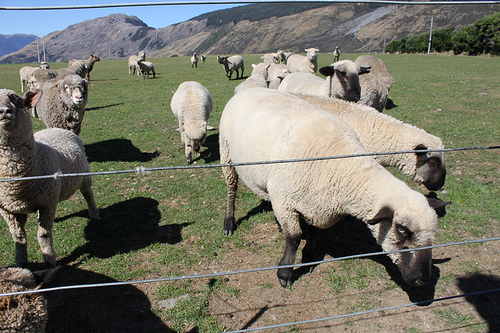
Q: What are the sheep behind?
A: Fence.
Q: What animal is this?
A: Sheep.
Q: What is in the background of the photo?
A: Mountains.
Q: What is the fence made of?
A: Metal.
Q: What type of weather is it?
A: Sunny.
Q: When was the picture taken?
A: In the day.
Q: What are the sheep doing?
A: Eating.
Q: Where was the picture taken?
A: In a sheep farm.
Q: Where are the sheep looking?
A: Ahead.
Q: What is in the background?
A: A mountain.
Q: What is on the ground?
A: Grass.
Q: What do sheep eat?
A: Grass.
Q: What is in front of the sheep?
A: Wire fence.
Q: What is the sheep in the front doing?
A: Eating.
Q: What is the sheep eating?
A: Grass.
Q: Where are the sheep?
A: Inside the fence.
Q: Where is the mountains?
A: In the distance.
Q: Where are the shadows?
A: On the ground.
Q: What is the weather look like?
A: Sunny.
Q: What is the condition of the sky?
A: Clear.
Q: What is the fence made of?
A: Wires.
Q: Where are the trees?
A: Other side of the fence.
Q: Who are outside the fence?
A: People taking pictures.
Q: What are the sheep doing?
A: Grazing.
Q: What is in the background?
A: Foothills.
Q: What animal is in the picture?
A: Sheep.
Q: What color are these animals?
A: White and black.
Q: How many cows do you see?
A: 0.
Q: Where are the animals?
A: In a field.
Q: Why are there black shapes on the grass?
A: They are shadows.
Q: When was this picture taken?
A: Day time.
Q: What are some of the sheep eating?
A: Grass.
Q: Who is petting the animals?
A: No one.